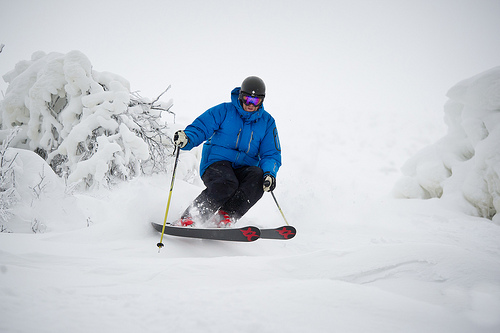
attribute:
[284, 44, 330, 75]
sky — white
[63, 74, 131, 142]
snow — white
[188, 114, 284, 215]
person — skiing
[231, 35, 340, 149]
helmet — black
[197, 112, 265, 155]
coat — blue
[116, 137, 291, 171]
hands — gloved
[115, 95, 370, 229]
man — skiing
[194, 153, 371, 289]
pants — black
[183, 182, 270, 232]
pants — black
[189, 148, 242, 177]
man — skiing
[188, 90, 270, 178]
coat — blue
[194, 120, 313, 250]
person — skiing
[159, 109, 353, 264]
person — skiing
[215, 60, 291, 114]
helmet — black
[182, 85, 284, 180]
coat — blue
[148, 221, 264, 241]
ski — black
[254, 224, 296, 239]
ski — black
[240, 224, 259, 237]
design — red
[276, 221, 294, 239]
design — red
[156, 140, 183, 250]
ski pole — yellow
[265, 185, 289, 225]
ski pole — yellow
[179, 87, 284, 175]
jacket — blue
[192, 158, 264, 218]
pants — black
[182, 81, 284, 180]
jacket — blue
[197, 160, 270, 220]
pants — black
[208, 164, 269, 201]
knees — bent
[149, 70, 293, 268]
person — skiing